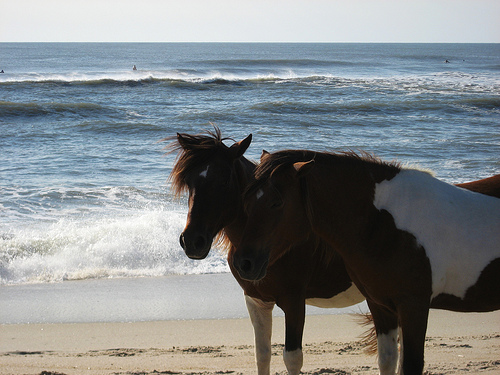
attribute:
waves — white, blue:
[2, 70, 499, 121]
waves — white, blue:
[13, 60, 197, 115]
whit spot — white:
[403, 182, 459, 242]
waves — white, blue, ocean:
[90, 46, 363, 128]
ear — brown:
[229, 132, 256, 155]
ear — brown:
[172, 131, 193, 149]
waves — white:
[1, 66, 493, 93]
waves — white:
[0, 205, 232, 279]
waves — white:
[1, 98, 123, 118]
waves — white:
[266, 98, 498, 110]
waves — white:
[204, 57, 339, 65]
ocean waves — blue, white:
[110, 185, 150, 208]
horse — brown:
[141, 121, 240, 263]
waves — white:
[4, 188, 229, 279]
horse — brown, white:
[224, 145, 497, 375]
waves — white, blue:
[1, 41, 495, 288]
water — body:
[0, 37, 497, 295]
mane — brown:
[158, 120, 262, 178]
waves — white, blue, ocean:
[5, 67, 496, 282]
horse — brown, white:
[171, 127, 362, 374]